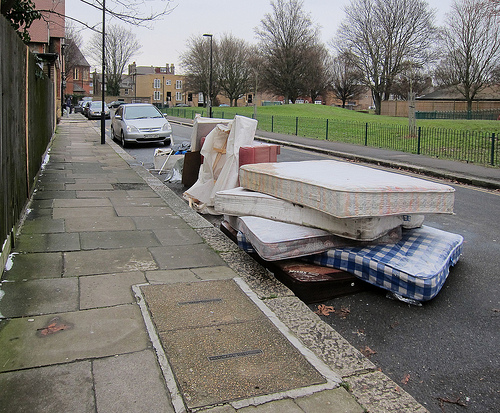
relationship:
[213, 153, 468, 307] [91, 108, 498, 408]
mattresses are in road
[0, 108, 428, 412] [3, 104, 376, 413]
sidewalk has slabs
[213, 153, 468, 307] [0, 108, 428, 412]
mattresses are next to sidewalk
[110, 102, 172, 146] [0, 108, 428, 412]
car next to sidewalk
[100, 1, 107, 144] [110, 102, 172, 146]
pole next to car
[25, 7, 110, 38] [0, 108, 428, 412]
branch hangs over sidewalk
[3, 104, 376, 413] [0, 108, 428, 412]
slabs are on sidewalk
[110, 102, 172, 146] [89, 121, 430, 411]
car next to curb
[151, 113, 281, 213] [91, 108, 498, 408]
garbage on road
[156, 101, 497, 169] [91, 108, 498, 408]
fence on side of road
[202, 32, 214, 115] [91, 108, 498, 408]
street light on side of road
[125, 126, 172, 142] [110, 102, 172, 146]
grill on front of car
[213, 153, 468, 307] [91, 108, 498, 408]
mattresses are on road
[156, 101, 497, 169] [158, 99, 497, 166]
fence in front of grass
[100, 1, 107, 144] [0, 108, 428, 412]
pole on edge of sidewalk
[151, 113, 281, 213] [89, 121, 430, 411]
garbage at side of curb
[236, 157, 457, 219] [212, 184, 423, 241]
mattress on top of mattress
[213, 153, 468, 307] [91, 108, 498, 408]
mattresses are on side of road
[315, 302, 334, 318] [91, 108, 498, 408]
leaf on road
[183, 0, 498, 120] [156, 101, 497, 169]
trees are inside of fence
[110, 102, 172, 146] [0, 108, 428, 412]
car by sidewalk